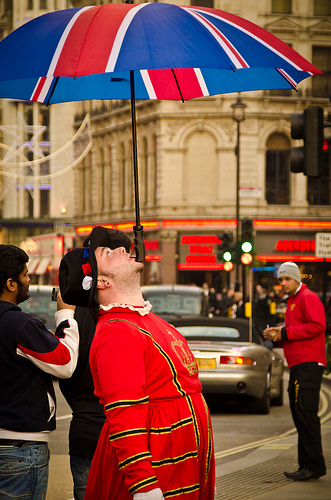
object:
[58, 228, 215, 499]
man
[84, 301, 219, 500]
jacket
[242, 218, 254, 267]
traffic light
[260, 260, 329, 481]
man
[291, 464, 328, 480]
boot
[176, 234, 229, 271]
sign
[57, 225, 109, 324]
hat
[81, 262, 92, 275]
red object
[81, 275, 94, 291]
white object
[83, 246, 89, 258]
blue object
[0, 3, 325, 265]
umbrella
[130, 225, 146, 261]
handle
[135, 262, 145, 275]
chin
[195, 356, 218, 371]
license plate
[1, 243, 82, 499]
man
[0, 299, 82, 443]
jacket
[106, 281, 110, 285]
earring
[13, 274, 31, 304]
beard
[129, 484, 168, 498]
glove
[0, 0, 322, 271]
union jack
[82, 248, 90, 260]
flower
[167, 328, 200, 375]
crown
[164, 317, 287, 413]
convertible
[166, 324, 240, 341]
soft top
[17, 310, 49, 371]
sleeve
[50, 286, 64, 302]
camera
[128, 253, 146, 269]
on man's mouth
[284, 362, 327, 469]
pants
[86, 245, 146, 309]
on mans head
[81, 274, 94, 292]
flowers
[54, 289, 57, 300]
picture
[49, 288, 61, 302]
phone